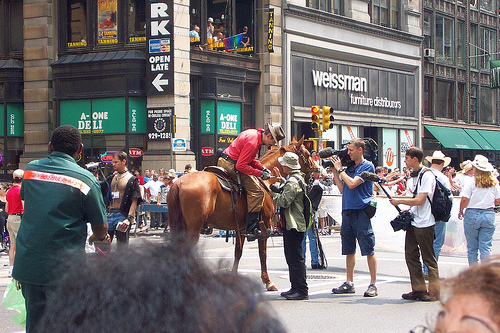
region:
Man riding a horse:
[160, 106, 333, 297]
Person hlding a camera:
[310, 137, 390, 195]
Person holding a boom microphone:
[353, 161, 430, 231]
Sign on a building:
[296, 58, 413, 135]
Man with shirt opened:
[99, 140, 141, 218]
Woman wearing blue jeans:
[460, 158, 499, 265]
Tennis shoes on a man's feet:
[332, 280, 384, 305]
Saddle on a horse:
[199, 155, 251, 209]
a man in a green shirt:
[13, 125, 109, 332]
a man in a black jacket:
[106, 151, 141, 248]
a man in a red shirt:
[216, 121, 286, 235]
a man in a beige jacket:
[268, 152, 323, 302]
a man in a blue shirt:
[321, 138, 378, 297]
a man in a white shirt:
[389, 147, 453, 303]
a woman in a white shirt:
[458, 153, 499, 268]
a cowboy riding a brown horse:
[167, 120, 319, 292]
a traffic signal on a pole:
[311, 103, 335, 147]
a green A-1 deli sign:
[58, 98, 148, 135]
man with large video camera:
[320, 135, 383, 298]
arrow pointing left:
[149, 70, 171, 95]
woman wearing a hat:
[458, 153, 494, 263]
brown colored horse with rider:
[168, 133, 320, 298]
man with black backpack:
[389, 147, 452, 302]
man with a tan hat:
[270, 148, 318, 303]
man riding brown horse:
[217, 108, 286, 240]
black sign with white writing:
[148, 107, 173, 142]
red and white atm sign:
[127, 145, 143, 158]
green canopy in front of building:
[425, 121, 498, 152]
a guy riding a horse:
[206, 102, 295, 187]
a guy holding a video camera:
[328, 137, 373, 197]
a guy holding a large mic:
[363, 168, 409, 216]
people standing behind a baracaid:
[137, 163, 169, 205]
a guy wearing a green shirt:
[38, 199, 112, 221]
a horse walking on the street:
[195, 135, 272, 283]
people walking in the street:
[428, 146, 498, 208]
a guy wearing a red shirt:
[223, 127, 258, 168]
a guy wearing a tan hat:
[249, 118, 281, 144]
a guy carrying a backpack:
[425, 167, 456, 229]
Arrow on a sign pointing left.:
[149, 72, 174, 97]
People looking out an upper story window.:
[206, 10, 229, 52]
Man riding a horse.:
[217, 118, 290, 238]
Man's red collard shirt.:
[219, 118, 265, 184]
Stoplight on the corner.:
[306, 103, 334, 132]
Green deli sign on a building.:
[57, 93, 147, 134]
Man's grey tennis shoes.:
[328, 278, 379, 298]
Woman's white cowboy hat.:
[461, 152, 492, 173]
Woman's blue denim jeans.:
[460, 206, 496, 276]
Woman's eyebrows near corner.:
[429, 303, 498, 329]